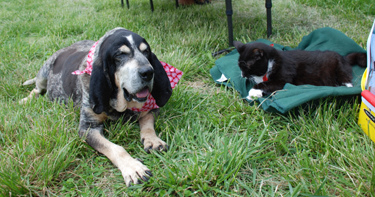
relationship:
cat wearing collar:
[233, 40, 367, 101] [261, 42, 274, 81]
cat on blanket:
[233, 40, 367, 101] [263, 67, 370, 108]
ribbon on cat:
[252, 56, 275, 85] [229, 32, 368, 95]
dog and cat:
[17, 27, 183, 187] [233, 40, 367, 101]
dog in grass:
[17, 27, 183, 187] [2, 2, 371, 193]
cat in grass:
[233, 40, 367, 101] [2, 2, 371, 193]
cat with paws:
[231, 38, 369, 110] [242, 82, 269, 105]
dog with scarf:
[55, 12, 193, 159] [70, 38, 185, 113]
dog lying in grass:
[17, 27, 183, 187] [6, 97, 277, 181]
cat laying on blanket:
[233, 40, 367, 101] [205, 24, 367, 112]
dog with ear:
[17, 27, 183, 187] [89, 47, 112, 115]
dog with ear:
[17, 27, 183, 187] [144, 51, 170, 102]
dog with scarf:
[17, 27, 183, 187] [70, 38, 185, 113]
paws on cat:
[247, 88, 261, 101] [229, 33, 365, 100]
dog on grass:
[17, 27, 183, 187] [2, 2, 371, 193]